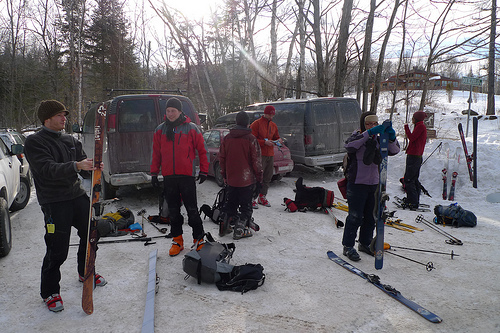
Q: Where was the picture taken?
A: It was taken at the parking lot.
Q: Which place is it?
A: It is a parking lot.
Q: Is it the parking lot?
A: Yes, it is the parking lot.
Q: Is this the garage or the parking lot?
A: It is the parking lot.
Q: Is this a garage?
A: No, it is a parking lot.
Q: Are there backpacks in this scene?
A: Yes, there is a backpack.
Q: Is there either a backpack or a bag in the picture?
A: Yes, there is a backpack.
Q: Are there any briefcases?
A: No, there are no briefcases.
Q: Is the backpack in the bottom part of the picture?
A: Yes, the backpack is in the bottom of the image.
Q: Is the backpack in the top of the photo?
A: No, the backpack is in the bottom of the image.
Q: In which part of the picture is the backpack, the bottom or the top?
A: The backpack is in the bottom of the image.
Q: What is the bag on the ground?
A: The bag is a backpack.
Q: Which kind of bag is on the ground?
A: The bag is a backpack.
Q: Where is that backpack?
A: The backpack is on the ground.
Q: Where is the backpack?
A: The backpack is on the ground.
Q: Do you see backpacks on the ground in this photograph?
A: Yes, there is a backpack on the ground.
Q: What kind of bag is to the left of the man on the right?
A: The bag is a backpack.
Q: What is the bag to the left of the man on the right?
A: The bag is a backpack.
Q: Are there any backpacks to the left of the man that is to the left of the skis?
A: Yes, there is a backpack to the left of the man.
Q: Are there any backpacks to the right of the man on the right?
A: No, the backpack is to the left of the man.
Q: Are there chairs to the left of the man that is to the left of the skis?
A: No, there is a backpack to the left of the man.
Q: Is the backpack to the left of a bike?
A: No, the backpack is to the left of a man.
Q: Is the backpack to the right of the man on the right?
A: No, the backpack is to the left of the man.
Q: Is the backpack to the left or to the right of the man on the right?
A: The backpack is to the left of the man.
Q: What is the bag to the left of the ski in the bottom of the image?
A: The bag is a backpack.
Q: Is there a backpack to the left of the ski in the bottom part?
A: Yes, there is a backpack to the left of the ski.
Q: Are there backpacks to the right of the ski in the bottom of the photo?
A: No, the backpack is to the left of the ski.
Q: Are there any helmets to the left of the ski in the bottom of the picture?
A: No, there is a backpack to the left of the ski.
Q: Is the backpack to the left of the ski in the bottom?
A: Yes, the backpack is to the left of the ski.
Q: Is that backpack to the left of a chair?
A: No, the backpack is to the left of the ski.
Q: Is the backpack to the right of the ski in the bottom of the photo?
A: No, the backpack is to the left of the ski.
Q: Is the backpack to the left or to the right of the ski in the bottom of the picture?
A: The backpack is to the left of the ski.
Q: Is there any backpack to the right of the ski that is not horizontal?
A: Yes, there is a backpack to the right of the ski.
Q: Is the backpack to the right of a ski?
A: Yes, the backpack is to the right of a ski.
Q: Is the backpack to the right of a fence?
A: No, the backpack is to the right of a ski.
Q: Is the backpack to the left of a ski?
A: No, the backpack is to the right of a ski.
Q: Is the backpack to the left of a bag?
A: Yes, the backpack is to the left of a bag.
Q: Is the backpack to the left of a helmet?
A: No, the backpack is to the left of a bag.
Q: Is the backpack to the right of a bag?
A: No, the backpack is to the left of a bag.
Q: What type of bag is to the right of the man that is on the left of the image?
A: The bag is a backpack.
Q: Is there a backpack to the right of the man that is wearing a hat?
A: Yes, there is a backpack to the right of the man.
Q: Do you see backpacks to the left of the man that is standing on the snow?
A: No, the backpack is to the right of the man.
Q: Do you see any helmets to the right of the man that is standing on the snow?
A: No, there is a backpack to the right of the man.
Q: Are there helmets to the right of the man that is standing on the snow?
A: No, there is a backpack to the right of the man.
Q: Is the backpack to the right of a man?
A: Yes, the backpack is to the right of a man.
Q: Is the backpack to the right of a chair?
A: No, the backpack is to the right of a man.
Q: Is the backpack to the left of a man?
A: No, the backpack is to the right of a man.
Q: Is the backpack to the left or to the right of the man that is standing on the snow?
A: The backpack is to the right of the man.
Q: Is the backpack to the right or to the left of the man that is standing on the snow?
A: The backpack is to the right of the man.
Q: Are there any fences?
A: No, there are no fences.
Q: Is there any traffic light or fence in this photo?
A: No, there are no fences or traffic lights.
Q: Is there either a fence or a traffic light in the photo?
A: No, there are no fences or traffic lights.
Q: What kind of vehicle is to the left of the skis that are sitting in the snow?
A: The vehicle is a van.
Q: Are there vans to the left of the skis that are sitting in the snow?
A: Yes, there is a van to the left of the skis.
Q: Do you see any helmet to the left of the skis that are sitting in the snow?
A: No, there is a van to the left of the skis.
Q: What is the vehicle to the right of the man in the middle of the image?
A: The vehicle is a van.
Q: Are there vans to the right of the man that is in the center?
A: Yes, there is a van to the right of the man.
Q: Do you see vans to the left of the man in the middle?
A: No, the van is to the right of the man.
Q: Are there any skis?
A: Yes, there are skis.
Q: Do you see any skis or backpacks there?
A: Yes, there are skis.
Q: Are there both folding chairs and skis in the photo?
A: No, there are skis but no folding chairs.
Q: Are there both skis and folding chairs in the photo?
A: No, there are skis but no folding chairs.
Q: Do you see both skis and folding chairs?
A: No, there are skis but no folding chairs.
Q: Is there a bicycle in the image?
A: No, there are no bicycles.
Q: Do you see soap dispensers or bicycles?
A: No, there are no bicycles or soap dispensers.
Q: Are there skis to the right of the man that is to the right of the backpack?
A: Yes, there are skis to the right of the man.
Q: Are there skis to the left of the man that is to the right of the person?
A: No, the skis are to the right of the man.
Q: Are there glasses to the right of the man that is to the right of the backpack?
A: No, there are skis to the right of the man.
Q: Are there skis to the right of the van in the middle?
A: Yes, there are skis to the right of the van.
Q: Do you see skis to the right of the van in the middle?
A: Yes, there are skis to the right of the van.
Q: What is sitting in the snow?
A: The skis are sitting in the snow.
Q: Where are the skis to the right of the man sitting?
A: The skis are sitting in the snow.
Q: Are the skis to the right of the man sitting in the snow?
A: Yes, the skis are sitting in the snow.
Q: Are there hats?
A: Yes, there is a hat.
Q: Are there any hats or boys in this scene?
A: Yes, there is a hat.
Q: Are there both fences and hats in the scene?
A: No, there is a hat but no fences.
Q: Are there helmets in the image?
A: No, there are no helmets.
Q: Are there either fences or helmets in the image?
A: No, there are no helmets or fences.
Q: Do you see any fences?
A: No, there are no fences.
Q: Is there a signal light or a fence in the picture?
A: No, there are no fences or traffic lights.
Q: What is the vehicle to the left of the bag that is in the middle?
A: The vehicle is a van.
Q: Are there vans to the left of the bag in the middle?
A: Yes, there is a van to the left of the bag.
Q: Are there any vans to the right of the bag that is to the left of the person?
A: No, the van is to the left of the bag.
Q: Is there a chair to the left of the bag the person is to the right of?
A: No, there is a van to the left of the bag.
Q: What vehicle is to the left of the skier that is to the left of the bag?
A: The vehicle is a van.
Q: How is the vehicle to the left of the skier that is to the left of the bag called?
A: The vehicle is a van.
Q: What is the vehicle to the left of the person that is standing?
A: The vehicle is a van.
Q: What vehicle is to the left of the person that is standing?
A: The vehicle is a van.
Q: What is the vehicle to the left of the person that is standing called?
A: The vehicle is a van.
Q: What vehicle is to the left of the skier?
A: The vehicle is a van.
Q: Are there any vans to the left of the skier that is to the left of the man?
A: Yes, there is a van to the left of the skier.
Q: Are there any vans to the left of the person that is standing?
A: Yes, there is a van to the left of the skier.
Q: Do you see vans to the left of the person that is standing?
A: Yes, there is a van to the left of the skier.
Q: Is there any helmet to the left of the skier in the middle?
A: No, there is a van to the left of the skier.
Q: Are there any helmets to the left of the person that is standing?
A: No, there is a van to the left of the skier.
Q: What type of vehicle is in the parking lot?
A: The vehicle is a van.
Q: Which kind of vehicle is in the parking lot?
A: The vehicle is a van.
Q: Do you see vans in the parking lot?
A: Yes, there is a van in the parking lot.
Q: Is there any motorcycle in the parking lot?
A: No, there is a van in the parking lot.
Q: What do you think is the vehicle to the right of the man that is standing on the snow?
A: The vehicle is a van.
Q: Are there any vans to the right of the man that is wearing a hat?
A: Yes, there is a van to the right of the man.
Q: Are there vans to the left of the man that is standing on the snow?
A: No, the van is to the right of the man.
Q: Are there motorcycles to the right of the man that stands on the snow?
A: No, there is a van to the right of the man.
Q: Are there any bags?
A: Yes, there is a bag.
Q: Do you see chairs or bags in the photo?
A: Yes, there is a bag.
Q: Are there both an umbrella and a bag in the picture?
A: No, there is a bag but no umbrellas.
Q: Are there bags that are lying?
A: Yes, there is a bag that is lying.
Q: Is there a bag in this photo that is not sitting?
A: Yes, there is a bag that is lying.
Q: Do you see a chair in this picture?
A: No, there are no chairs.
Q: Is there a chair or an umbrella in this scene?
A: No, there are no chairs or umbrellas.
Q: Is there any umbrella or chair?
A: No, there are no chairs or umbrellas.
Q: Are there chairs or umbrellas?
A: No, there are no chairs or umbrellas.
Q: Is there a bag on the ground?
A: Yes, there is a bag on the ground.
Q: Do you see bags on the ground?
A: Yes, there is a bag on the ground.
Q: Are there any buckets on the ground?
A: No, there is a bag on the ground.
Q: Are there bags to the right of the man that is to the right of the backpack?
A: Yes, there is a bag to the right of the man.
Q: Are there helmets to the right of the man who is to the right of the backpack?
A: No, there is a bag to the right of the man.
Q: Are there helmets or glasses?
A: No, there are no helmets or glasses.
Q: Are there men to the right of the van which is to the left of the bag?
A: No, the man is to the left of the van.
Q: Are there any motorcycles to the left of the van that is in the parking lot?
A: No, there is a man to the left of the van.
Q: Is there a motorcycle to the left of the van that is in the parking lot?
A: No, there is a man to the left of the van.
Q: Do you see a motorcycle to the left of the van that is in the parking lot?
A: No, there is a man to the left of the van.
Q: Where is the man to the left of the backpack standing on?
A: The man is standing on the snow.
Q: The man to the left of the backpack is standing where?
A: The man is standing on the snow.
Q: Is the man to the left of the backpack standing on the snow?
A: Yes, the man is standing on the snow.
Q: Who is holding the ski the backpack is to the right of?
A: The man is holding the ski.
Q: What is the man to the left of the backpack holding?
A: The man is holding the ski.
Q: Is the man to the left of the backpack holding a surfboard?
A: No, the man is holding the ski.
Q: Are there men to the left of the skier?
A: Yes, there is a man to the left of the skier.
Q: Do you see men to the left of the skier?
A: Yes, there is a man to the left of the skier.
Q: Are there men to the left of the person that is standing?
A: Yes, there is a man to the left of the skier.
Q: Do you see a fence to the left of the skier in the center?
A: No, there is a man to the left of the skier.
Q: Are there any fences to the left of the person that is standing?
A: No, there is a man to the left of the skier.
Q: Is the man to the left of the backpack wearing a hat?
A: Yes, the man is wearing a hat.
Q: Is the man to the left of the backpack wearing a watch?
A: No, the man is wearing a hat.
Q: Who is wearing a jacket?
A: The man is wearing a jacket.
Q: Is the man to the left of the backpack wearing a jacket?
A: Yes, the man is wearing a jacket.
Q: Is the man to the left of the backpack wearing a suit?
A: No, the man is wearing a jacket.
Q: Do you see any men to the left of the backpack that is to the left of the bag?
A: Yes, there is a man to the left of the backpack.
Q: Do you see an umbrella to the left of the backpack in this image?
A: No, there is a man to the left of the backpack.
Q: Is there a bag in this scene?
A: Yes, there is a bag.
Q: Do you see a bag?
A: Yes, there is a bag.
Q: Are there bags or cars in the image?
A: Yes, there is a bag.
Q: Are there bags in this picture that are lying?
A: Yes, there is a bag that is lying.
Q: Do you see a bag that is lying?
A: Yes, there is a bag that is lying.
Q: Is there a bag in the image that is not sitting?
A: Yes, there is a bag that is lying.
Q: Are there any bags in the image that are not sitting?
A: Yes, there is a bag that is lying.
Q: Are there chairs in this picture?
A: No, there are no chairs.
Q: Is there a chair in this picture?
A: No, there are no chairs.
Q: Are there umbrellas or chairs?
A: No, there are no chairs or umbrellas.